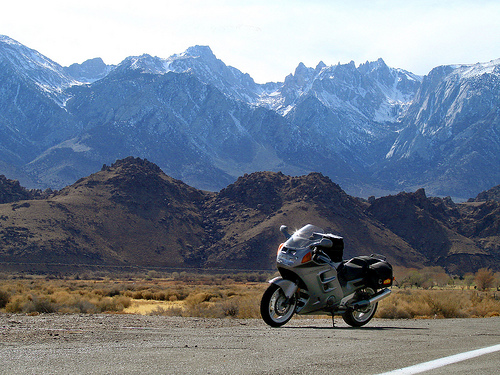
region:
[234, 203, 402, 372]
a gray motorcycle sits on the road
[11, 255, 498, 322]
the grass is brown and patchy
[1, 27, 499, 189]
the mountains are blue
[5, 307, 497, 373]
the road is gray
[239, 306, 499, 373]
the road has a white line on it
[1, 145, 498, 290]
behind the motorcycle are big dirt hills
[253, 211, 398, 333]
the bike has side mirrors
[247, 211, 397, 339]
the bike is held up by a kickstand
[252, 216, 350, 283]
the bike has lights on the front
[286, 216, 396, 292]
the bike has a black seat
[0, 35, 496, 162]
soaring snow topped mountains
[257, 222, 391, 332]
sleek silver and black motorcycle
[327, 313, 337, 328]
kickstand holding motorcycle upright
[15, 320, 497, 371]
asphalt shoulder of roadway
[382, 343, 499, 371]
white stripe marking edge of roadway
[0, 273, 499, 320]
dry grass and shrubs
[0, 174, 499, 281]
low rolling foothills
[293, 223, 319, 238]
sloping motorcycle windshield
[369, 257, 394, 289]
storage container on side of seat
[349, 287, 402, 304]
motorcycle exhaust pipe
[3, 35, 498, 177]
Mountains in the background of photo.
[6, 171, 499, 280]
Dirt mounds in front of the mountains in the background.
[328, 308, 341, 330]
Kickstand of the motorcycle that is parked on the road.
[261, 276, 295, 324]
Front wheel of the motorcycle.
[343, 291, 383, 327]
Rear wheel of the motorcycle.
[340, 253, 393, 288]
Black seat of the motorcycle.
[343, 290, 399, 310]
Tailpipe in the rear of the motorcycle.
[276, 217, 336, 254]
Side view mirrors on the motorcycle.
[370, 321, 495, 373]
White line on the street.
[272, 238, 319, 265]
Lights on the front of the motorcycle.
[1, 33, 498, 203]
large mountain range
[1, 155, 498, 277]
small hills in front of mountains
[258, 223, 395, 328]
high performance silver motorcycle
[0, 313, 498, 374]
asphalt painted with white line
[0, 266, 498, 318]
grassy area between asphalt and hills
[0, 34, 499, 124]
snowy areas on mountaintops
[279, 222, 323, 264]
motorcycle windshield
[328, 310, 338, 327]
motorcycle kickstand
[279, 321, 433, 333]
shadow of motorcycle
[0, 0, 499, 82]
pale blue sky above mountains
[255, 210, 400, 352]
SILVER MOTORCYCLE ON THE SIDE OF THE ROAD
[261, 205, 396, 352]
MOTORCYCLE WITH NO ONE ON IT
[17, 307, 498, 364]
SIDE OF THE ROAD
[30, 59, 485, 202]
MOUNTAINS IN THE DISTANCE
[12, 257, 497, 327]
SPARSE VEGETATION IN A FIELD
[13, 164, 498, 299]
HILLS NOT TOO FAR OFF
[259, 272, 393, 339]
WHEELS OF THE MOTORCYCLE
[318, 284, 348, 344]
KICKSTAND USED TO HOLD UP THE BIKE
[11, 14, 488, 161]
CLEAR SKY ABOVE THE MOUNTAINS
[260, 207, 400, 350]
BIKE WAITING FOR A RIDER